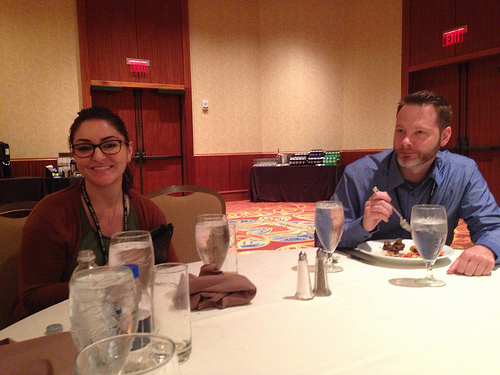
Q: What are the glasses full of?
A: Water.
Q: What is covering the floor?
A: Brightly colored carpet.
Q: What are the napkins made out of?
A: Brown cloth.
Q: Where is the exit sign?
A: Over the door.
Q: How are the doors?
A: In pairs.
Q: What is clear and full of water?
A: Glasses.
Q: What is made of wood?
A: Doors.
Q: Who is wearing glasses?
A: The woman.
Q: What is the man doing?
A: Eating.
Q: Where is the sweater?
A: On the woman.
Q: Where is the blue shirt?
A: On the man.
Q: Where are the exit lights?
A: Over the door.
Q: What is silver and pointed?
A: Fork.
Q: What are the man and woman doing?
A: Eating.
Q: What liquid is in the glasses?
A: Water.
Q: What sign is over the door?
A: Exit.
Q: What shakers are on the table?
A: Salt & pepper.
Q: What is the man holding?
A: Fork.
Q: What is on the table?
A: Tablecloth.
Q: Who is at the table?
A: A man and a woman.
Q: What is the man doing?
A: Eating.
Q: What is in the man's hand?
A: A fork.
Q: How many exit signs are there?
A: Two.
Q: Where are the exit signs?
A: Over the doors.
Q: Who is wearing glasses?
A: The woman.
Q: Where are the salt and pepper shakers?
A: On the table.